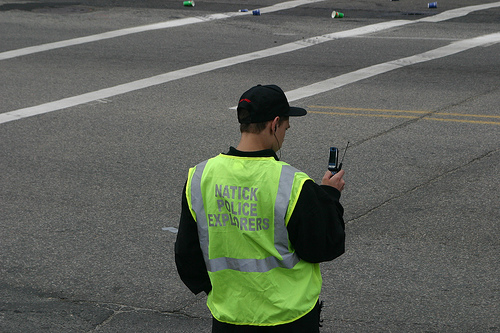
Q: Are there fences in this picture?
A: No, there are no fences.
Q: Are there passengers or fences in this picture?
A: No, there are no fences or passengers.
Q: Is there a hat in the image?
A: Yes, there is a hat.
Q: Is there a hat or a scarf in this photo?
A: Yes, there is a hat.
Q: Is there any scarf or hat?
A: Yes, there is a hat.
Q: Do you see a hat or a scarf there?
A: Yes, there is a hat.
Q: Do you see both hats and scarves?
A: No, there is a hat but no scarves.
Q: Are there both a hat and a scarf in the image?
A: No, there is a hat but no scarves.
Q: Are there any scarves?
A: No, there are no scarves.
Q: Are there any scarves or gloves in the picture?
A: No, there are no scarves or gloves.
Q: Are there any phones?
A: Yes, there is a phone.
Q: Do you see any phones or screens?
A: Yes, there is a phone.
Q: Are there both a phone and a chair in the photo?
A: No, there is a phone but no chairs.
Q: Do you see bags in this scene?
A: No, there are no bags.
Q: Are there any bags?
A: No, there are no bags.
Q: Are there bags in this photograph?
A: No, there are no bags.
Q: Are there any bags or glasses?
A: No, there are no bags or glasses.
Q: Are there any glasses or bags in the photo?
A: No, there are no bags or glasses.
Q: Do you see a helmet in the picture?
A: No, there are no helmets.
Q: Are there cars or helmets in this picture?
A: No, there are no helmets or cars.